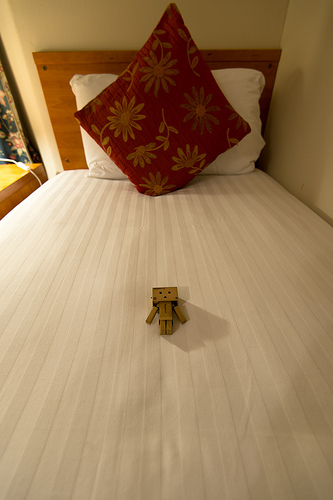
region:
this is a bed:
[44, 204, 281, 479]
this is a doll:
[149, 286, 185, 327]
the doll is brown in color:
[153, 293, 164, 300]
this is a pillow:
[124, 75, 203, 153]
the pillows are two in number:
[81, 75, 239, 173]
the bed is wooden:
[41, 80, 70, 119]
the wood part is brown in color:
[53, 88, 72, 127]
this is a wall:
[284, 76, 324, 181]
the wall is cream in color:
[287, 61, 318, 109]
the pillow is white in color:
[226, 72, 249, 95]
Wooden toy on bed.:
[146, 285, 188, 336]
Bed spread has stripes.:
[5, 168, 331, 499]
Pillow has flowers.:
[72, 1, 254, 196]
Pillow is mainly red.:
[73, 4, 252, 197]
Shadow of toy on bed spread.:
[160, 294, 228, 352]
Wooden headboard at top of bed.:
[32, 48, 281, 177]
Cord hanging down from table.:
[0, 156, 41, 186]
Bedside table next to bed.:
[0, 157, 44, 213]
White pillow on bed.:
[68, 66, 269, 180]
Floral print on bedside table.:
[0, 69, 37, 171]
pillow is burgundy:
[55, 6, 258, 197]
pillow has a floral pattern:
[77, 16, 252, 197]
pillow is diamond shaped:
[74, 9, 256, 202]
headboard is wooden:
[29, 46, 280, 181]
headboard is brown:
[23, 48, 277, 207]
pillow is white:
[63, 71, 275, 180]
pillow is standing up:
[69, 3, 259, 208]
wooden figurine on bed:
[138, 284, 188, 346]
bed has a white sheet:
[15, 149, 320, 496]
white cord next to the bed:
[1, 143, 44, 194]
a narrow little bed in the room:
[1, 170, 324, 483]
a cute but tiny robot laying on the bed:
[145, 283, 189, 336]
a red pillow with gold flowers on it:
[83, 26, 254, 191]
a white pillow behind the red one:
[65, 69, 262, 172]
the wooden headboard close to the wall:
[32, 46, 283, 182]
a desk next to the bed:
[4, 161, 48, 220]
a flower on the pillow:
[181, 88, 221, 143]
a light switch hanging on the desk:
[0, 154, 43, 184]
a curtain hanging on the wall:
[1, 105, 40, 165]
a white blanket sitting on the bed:
[25, 374, 328, 486]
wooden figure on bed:
[118, 268, 211, 374]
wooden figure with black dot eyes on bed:
[97, 273, 217, 371]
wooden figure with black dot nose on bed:
[142, 241, 199, 367]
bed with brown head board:
[32, 38, 331, 340]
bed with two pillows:
[25, 34, 327, 270]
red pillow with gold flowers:
[20, 43, 274, 192]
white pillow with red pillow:
[19, 56, 306, 209]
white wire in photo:
[2, 105, 49, 227]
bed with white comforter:
[24, 42, 282, 498]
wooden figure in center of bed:
[122, 264, 220, 379]